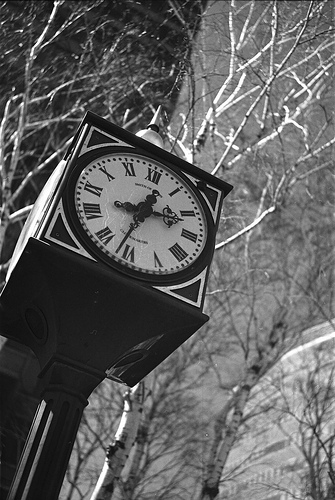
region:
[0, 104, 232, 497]
clock on a pole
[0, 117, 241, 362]
white squared clock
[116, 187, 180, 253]
two black clock hands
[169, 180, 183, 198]
numer one in roman numerals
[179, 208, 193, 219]
Number two in roman numerals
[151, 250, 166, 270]
number five in roman numerals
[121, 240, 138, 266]
number six in roman numerals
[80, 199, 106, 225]
number eight in roman numerals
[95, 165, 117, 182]
numer ten in roman numerals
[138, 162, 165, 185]
numer twelve in roman numerals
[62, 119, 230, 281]
Clock on a building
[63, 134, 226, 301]
clock on a tower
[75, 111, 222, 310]
clock on a tower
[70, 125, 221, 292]
clock on a tower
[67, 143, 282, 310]
clock on a tower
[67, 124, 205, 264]
clock on a tower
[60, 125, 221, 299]
clock on a tower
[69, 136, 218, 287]
clock on a tower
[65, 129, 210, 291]
clock on a tower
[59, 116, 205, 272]
clock on a tower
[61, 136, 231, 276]
a clock in the top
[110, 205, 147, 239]
hands of the clock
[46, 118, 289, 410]
a wall clok in tower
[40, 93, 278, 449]
a beautiful view of clock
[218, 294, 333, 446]
a beautiful view of trees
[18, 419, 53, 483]
a curve in the tower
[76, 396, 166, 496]
a tree in the back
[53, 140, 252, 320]
a clear view of clock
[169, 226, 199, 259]
roman numerials on the clock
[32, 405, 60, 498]
the pole is black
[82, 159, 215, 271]
a clock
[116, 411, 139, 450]
the tree trunk of the tree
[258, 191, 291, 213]
the tree branches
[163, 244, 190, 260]
the roman numerials are black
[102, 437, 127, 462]
black spots on the tree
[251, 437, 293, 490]
a building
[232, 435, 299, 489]
the building is white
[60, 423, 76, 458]
a shadow on the pole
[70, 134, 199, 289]
the clock shows 2:32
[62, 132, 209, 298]
the clock shows 2:32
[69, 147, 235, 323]
the clock shows 2:32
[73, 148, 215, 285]
the clock shows 2:32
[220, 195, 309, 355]
the trees are bare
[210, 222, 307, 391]
the trees are bare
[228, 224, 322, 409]
the trees are bare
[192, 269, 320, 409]
the trees are bare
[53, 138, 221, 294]
clock with black numerals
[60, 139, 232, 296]
clock with black numerals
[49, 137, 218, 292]
clock on box face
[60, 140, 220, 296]
clock on box is round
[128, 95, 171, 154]
globe on top of box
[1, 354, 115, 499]
pole holding clock face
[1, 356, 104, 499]
pole is metal and black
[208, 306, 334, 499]
building behind thin trees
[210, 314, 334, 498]
building behind trees is large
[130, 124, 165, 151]
round globe on box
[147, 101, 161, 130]
cone on top of globe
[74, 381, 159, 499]
tree is thin and white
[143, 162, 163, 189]
roman number twelve on clock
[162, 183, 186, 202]
roman number one on clock